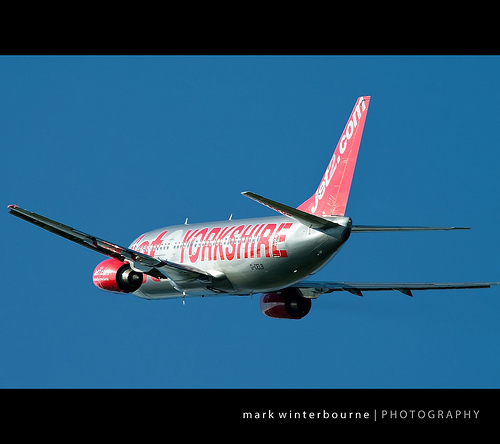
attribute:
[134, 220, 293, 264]
letters — red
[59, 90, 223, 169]
sky — blue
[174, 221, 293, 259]
name — red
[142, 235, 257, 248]
windows — many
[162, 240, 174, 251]
door — closed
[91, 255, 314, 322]
engine — double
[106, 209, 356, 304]
plane — silver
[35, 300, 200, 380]
sky — blue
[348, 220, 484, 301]
wings — black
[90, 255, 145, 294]
piper — red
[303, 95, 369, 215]
tail — red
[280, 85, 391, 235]
red tail — red 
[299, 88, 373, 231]
words — white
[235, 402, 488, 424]
words — white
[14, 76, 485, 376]
sky — blue 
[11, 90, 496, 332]
plane — grey , red 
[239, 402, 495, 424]
letters — white 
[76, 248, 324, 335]
engine — red 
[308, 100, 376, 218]
letters — white 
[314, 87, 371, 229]
tail — red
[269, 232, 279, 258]
door — closed